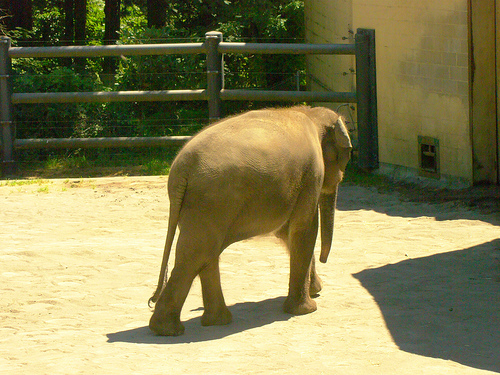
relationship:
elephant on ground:
[120, 47, 428, 322] [26, 201, 123, 358]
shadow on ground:
[351, 218, 496, 371] [317, 264, 480, 365]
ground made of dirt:
[2, 174, 499, 374] [2, 174, 498, 373]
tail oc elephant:
[141, 170, 181, 320] [109, 92, 384, 329]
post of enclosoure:
[204, 28, 226, 124] [1, 32, 496, 372]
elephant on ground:
[147, 105, 353, 336] [16, 175, 147, 351]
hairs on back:
[169, 100, 320, 143] [186, 104, 306, 131]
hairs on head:
[169, 100, 320, 143] [307, 104, 355, 262]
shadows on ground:
[336, 187, 499, 364] [365, 193, 485, 359]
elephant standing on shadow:
[147, 105, 353, 336] [352, 230, 483, 353]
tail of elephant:
[147, 150, 194, 309] [86, 55, 431, 372]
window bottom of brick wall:
[412, 136, 443, 173] [350, 0, 473, 180]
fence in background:
[1, 25, 379, 177] [8, 7, 264, 109]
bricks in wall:
[380, 26, 472, 173] [373, 27, 496, 174]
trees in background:
[12, 29, 307, 153] [8, 7, 264, 109]